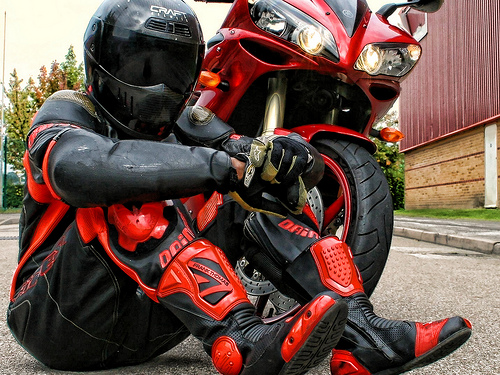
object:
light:
[293, 21, 328, 56]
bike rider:
[7, 3, 472, 374]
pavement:
[1, 214, 500, 373]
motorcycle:
[187, 0, 445, 321]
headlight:
[248, 2, 290, 38]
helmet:
[82, 0, 204, 142]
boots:
[154, 239, 345, 374]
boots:
[280, 232, 472, 373]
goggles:
[102, 22, 205, 95]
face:
[95, 24, 192, 120]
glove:
[247, 132, 308, 187]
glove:
[231, 153, 308, 218]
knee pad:
[105, 194, 172, 252]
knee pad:
[289, 195, 322, 231]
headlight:
[356, 45, 383, 74]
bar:
[258, 69, 287, 136]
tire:
[311, 140, 394, 315]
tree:
[0, 66, 36, 174]